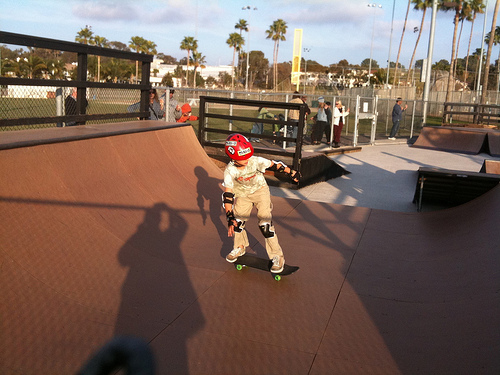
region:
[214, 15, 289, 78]
Palm trees are in the background.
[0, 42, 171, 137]
A fence can be scene.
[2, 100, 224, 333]
A skating ramp.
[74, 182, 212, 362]
The shadow of the photographer.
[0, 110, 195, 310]
The skate ramp is brown.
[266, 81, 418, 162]
A group of people.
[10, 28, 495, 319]
A skate park picture.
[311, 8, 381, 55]
Clouds are in the sky.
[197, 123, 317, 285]
The skateboarder is wearing safety gear.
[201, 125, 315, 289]
The skater is wearing a red helmet.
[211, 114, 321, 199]
the helmet is red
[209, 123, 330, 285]
the little boy is skateboarding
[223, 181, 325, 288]
the little boy has on khaki pants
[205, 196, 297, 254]
the little boy has on protective gear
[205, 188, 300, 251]
the protective gear is black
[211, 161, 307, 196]
the boy's shirt is white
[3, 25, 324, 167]
the ramp has metal railings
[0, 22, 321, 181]
the metal railings are black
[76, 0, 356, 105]
palm trees are in the background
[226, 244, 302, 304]
the skateboard has green wheels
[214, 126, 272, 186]
boy wears red helmet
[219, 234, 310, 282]
skateboard is black with green wheels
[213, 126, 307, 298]
the boy is riding a skateboard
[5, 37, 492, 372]
skate ramp is brown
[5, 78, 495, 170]
chain link fence behind the skate ramp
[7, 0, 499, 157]
palm trees in the background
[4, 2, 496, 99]
sky is partly cloudy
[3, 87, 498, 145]
green grass behind the fence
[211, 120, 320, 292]
boy wears black elbow and knee pads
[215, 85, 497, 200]
extra skate ramp parts in the background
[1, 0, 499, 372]
park with skateboarding area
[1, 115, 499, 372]
skateboard ramp at park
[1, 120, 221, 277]
a skateboard ramp slope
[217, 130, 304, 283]
a skateboarder near the ramp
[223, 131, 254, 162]
a red skateboarding helmet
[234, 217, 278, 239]
protection pads on knees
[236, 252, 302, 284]
black skateboard with green wheels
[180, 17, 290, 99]
palm trees at the park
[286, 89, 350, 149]
skateboarding spectators at the park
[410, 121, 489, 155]
a short skateboarding ramp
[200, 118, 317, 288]
Kid skating in a ramp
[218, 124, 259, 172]
Helmet is color red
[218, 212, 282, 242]
Knees protected with knee pads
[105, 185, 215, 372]
Shadow of person cas on the ramp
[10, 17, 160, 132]
Fence is brown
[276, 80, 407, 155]
People stand outside ramp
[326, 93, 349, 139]
Woman wears white jacket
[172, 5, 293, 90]
Palm trees in the background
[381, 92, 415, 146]
Man stands near an fence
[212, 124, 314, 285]
Kid wearing white shirt